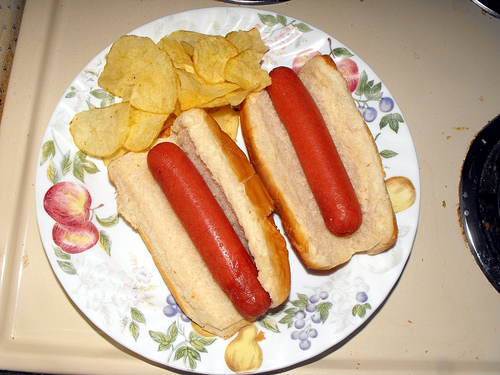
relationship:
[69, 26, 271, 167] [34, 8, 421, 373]
chips on plate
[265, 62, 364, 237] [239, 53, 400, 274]
dog on bun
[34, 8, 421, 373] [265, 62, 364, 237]
plate has dog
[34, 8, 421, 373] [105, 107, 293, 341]
plate of hotdogs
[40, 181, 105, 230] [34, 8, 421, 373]
apple on plate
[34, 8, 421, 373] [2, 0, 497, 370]
plate on table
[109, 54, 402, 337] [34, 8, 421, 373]
hotdogs on plate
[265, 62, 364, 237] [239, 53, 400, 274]
dog in bun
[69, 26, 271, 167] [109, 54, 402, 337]
chips near hotdogs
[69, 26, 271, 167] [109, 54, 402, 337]
chips and hotdogs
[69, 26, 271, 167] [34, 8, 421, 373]
chips in plate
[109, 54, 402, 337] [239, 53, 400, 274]
hotdogs have bun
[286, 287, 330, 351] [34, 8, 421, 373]
grapes on plate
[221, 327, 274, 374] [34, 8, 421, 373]
pear on plate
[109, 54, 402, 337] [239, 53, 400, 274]
hotdogs in bun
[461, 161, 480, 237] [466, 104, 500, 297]
edge of burner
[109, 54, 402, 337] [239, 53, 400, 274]
hotdogs on bun